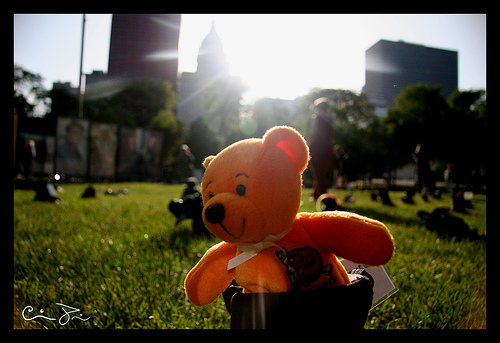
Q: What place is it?
A: It is a field.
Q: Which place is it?
A: It is a field.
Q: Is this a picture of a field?
A: Yes, it is showing a field.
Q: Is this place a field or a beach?
A: It is a field.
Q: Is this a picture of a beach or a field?
A: It is showing a field.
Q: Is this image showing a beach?
A: No, the picture is showing a field.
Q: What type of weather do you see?
A: It is clear.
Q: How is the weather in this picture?
A: It is clear.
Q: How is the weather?
A: It is clear.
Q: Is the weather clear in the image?
A: Yes, it is clear.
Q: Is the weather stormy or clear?
A: It is clear.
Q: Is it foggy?
A: No, it is clear.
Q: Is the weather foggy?
A: No, it is clear.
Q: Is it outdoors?
A: Yes, it is outdoors.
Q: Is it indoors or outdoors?
A: It is outdoors.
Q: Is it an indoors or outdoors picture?
A: It is outdoors.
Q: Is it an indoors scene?
A: No, it is outdoors.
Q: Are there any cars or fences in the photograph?
A: No, there are no cars or fences.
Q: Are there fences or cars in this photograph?
A: No, there are no cars or fences.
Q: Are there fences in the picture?
A: No, there are no fences.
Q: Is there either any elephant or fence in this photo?
A: No, there are no fences or elephants.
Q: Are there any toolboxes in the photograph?
A: No, there are no toolboxes.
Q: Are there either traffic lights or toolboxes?
A: No, there are no toolboxes or traffic lights.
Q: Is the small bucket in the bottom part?
A: Yes, the bucket is in the bottom of the image.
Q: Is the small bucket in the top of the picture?
A: No, the bucket is in the bottom of the image.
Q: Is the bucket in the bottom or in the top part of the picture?
A: The bucket is in the bottom of the image.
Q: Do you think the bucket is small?
A: Yes, the bucket is small.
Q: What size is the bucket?
A: The bucket is small.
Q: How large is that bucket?
A: The bucket is small.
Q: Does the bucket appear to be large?
A: No, the bucket is small.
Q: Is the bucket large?
A: No, the bucket is small.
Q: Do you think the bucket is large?
A: No, the bucket is small.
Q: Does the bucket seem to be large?
A: No, the bucket is small.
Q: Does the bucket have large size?
A: No, the bucket is small.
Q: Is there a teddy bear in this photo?
A: Yes, there is a teddy bear.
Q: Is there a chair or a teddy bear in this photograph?
A: Yes, there is a teddy bear.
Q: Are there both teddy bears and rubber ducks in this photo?
A: No, there is a teddy bear but no rubber ducks.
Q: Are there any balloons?
A: No, there are no balloons.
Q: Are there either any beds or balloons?
A: No, there are no balloons or beds.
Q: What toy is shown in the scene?
A: The toy is a teddy bear.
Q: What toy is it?
A: The toy is a teddy bear.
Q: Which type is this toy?
A: This is a teddy bear.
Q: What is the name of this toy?
A: This is a teddy bear.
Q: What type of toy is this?
A: This is a teddy bear.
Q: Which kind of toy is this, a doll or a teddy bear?
A: This is a teddy bear.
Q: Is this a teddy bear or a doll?
A: This is a teddy bear.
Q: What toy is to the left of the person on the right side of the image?
A: The toy is a teddy bear.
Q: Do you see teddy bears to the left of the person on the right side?
A: Yes, there is a teddy bear to the left of the person.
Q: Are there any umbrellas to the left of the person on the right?
A: No, there is a teddy bear to the left of the person.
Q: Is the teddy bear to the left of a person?
A: Yes, the teddy bear is to the left of a person.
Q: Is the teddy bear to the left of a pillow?
A: No, the teddy bear is to the left of a person.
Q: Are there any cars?
A: No, there are no cars.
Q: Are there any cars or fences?
A: No, there are no cars or fences.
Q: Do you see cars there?
A: No, there are no cars.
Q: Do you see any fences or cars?
A: No, there are no cars or fences.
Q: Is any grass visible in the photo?
A: Yes, there is grass.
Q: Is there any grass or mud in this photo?
A: Yes, there is grass.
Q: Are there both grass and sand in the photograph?
A: No, there is grass but no sand.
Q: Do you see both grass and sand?
A: No, there is grass but no sand.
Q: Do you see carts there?
A: No, there are no carts.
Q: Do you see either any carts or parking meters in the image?
A: No, there are no carts or parking meters.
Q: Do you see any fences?
A: No, there are no fences.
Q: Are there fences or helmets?
A: No, there are no fences or helmets.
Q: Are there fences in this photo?
A: No, there are no fences.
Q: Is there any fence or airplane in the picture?
A: No, there are no fences or airplanes.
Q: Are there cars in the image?
A: No, there are no cars.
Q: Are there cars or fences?
A: No, there are no cars or fences.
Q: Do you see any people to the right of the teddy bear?
A: Yes, there is a person to the right of the teddy bear.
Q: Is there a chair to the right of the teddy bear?
A: No, there is a person to the right of the teddy bear.